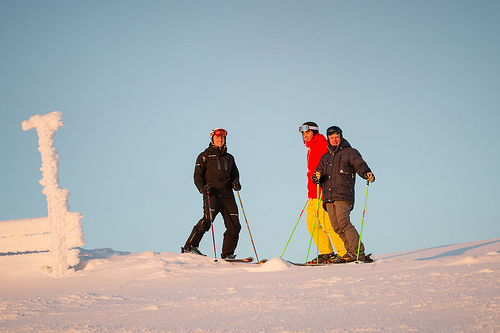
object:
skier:
[298, 122, 348, 263]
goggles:
[298, 125, 308, 132]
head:
[302, 121, 319, 140]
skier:
[184, 128, 241, 259]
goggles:
[214, 129, 226, 135]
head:
[210, 128, 228, 147]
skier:
[312, 126, 376, 264]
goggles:
[328, 127, 341, 132]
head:
[327, 126, 342, 145]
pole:
[236, 191, 259, 263]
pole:
[207, 192, 216, 259]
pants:
[307, 199, 347, 258]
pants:
[326, 201, 364, 260]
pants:
[184, 193, 241, 258]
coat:
[306, 136, 327, 199]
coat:
[311, 147, 371, 210]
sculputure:
[21, 111, 67, 274]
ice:
[0, 213, 81, 270]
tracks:
[296, 276, 363, 286]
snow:
[1, 277, 500, 332]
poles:
[280, 199, 310, 259]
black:
[208, 170, 230, 184]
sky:
[0, 0, 499, 240]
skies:
[287, 261, 321, 266]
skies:
[225, 257, 253, 262]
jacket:
[194, 144, 240, 199]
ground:
[0, 240, 497, 329]